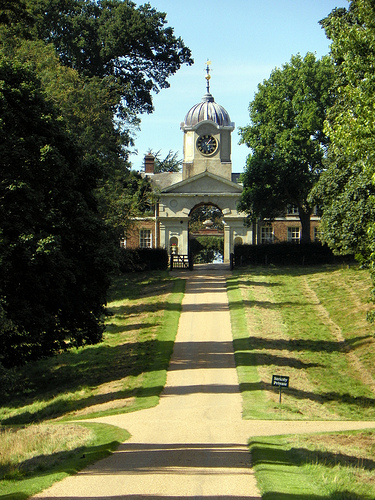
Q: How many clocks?
A: 1.